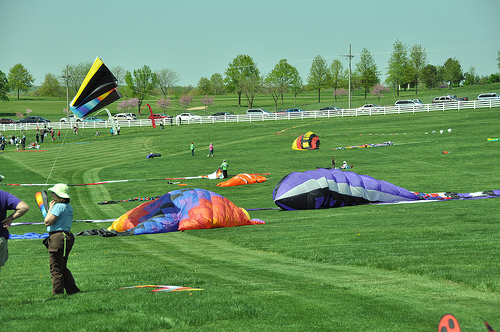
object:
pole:
[349, 42, 352, 115]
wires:
[352, 44, 484, 56]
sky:
[3, 0, 484, 84]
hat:
[48, 183, 72, 199]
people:
[18, 134, 26, 150]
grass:
[0, 83, 500, 326]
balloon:
[73, 188, 266, 236]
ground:
[0, 85, 499, 328]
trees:
[118, 63, 160, 117]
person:
[43, 182, 80, 294]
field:
[0, 105, 499, 332]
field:
[0, 84, 499, 332]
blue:
[274, 168, 500, 200]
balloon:
[273, 168, 422, 211]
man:
[0, 174, 30, 265]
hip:
[1, 237, 8, 254]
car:
[246, 109, 272, 118]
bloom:
[156, 95, 172, 108]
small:
[145, 134, 190, 153]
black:
[72, 63, 123, 117]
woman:
[207, 142, 214, 157]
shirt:
[209, 145, 213, 150]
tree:
[6, 61, 35, 100]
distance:
[0, 79, 500, 130]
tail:
[405, 190, 500, 203]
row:
[1, 50, 500, 118]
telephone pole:
[338, 41, 354, 116]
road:
[187, 105, 208, 110]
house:
[407, 76, 468, 88]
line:
[20, 96, 385, 102]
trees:
[116, 97, 140, 113]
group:
[1, 124, 81, 152]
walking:
[1, 137, 155, 182]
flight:
[139, 103, 157, 128]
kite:
[290, 131, 321, 152]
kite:
[217, 173, 268, 187]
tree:
[223, 52, 265, 107]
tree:
[265, 59, 301, 105]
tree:
[36, 73, 66, 98]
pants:
[47, 230, 80, 295]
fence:
[0, 99, 500, 131]